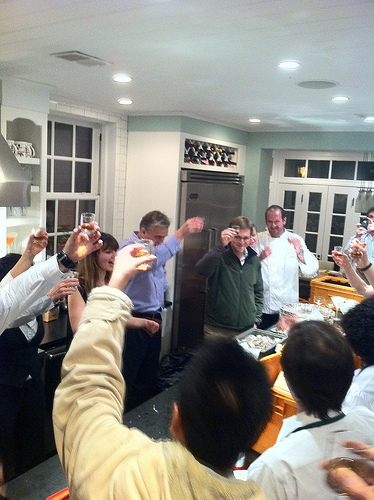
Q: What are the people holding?
A: Glasses.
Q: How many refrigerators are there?
A: One.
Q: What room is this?
A: The kitchen.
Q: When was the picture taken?
A: At night.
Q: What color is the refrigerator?
A: Silver.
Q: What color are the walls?
A: White and green.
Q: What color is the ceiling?
A: White.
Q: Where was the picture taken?
A: In a kitchen.